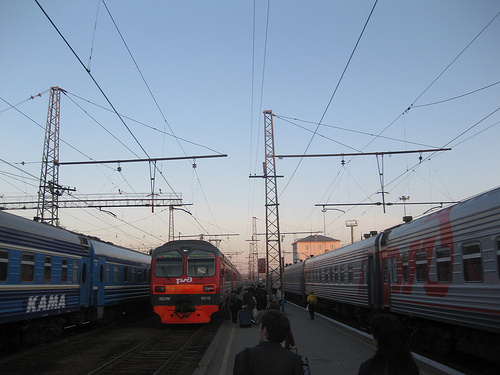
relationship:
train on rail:
[152, 237, 243, 324] [83, 290, 230, 374]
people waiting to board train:
[233, 300, 253, 329] [152, 235, 252, 326]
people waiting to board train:
[257, 283, 267, 310] [152, 235, 252, 326]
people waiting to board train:
[226, 294, 241, 322] [152, 235, 252, 326]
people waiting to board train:
[243, 284, 253, 306] [152, 235, 252, 326]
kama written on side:
[21, 290, 72, 315] [6, 226, 86, 283]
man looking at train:
[224, 309, 305, 372] [145, 226, 239, 329]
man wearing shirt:
[230, 309, 311, 375] [305, 294, 318, 300]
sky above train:
[4, 0, 494, 272] [151, 242, 234, 319]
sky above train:
[4, 0, 494, 272] [293, 206, 499, 316]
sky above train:
[4, 0, 494, 272] [0, 207, 150, 326]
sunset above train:
[88, 233, 423, 275] [271, 185, 497, 329]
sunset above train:
[88, 233, 423, 275] [152, 237, 243, 324]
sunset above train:
[88, 233, 423, 275] [0, 212, 151, 349]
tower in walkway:
[247, 88, 291, 321] [239, 272, 361, 372]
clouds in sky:
[30, 135, 471, 254] [0, 0, 498, 188]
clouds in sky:
[55, 200, 395, 277] [4, 0, 494, 272]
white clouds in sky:
[101, 72, 304, 216] [4, 0, 494, 272]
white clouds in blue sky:
[338, 49, 420, 126] [208, 31, 348, 101]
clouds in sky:
[254, 78, 378, 179] [424, 24, 477, 55]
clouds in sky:
[312, 93, 494, 184] [4, 0, 494, 272]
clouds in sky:
[73, 202, 416, 275] [4, 0, 494, 272]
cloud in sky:
[318, 203, 410, 248] [4, 0, 494, 272]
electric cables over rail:
[0, 0, 499, 270] [83, 290, 230, 374]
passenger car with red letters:
[374, 182, 499, 337] [356, 200, 457, 306]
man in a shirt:
[230, 309, 311, 375] [303, 293, 322, 304]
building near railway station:
[288, 227, 358, 267] [0, 155, 499, 374]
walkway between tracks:
[277, 274, 372, 369] [298, 293, 418, 360]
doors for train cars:
[77, 257, 110, 315] [2, 211, 154, 337]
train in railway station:
[152, 237, 243, 324] [17, 70, 477, 370]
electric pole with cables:
[259, 109, 284, 309] [268, 107, 440, 155]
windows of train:
[11, 253, 86, 286] [4, 206, 154, 334]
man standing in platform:
[230, 309, 311, 375] [191, 280, 465, 373]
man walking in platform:
[230, 309, 311, 375] [191, 280, 465, 373]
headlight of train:
[151, 280, 215, 294] [147, 238, 248, 333]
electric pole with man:
[259, 107, 289, 309] [230, 309, 311, 375]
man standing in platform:
[230, 309, 311, 375] [173, 265, 462, 373]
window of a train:
[155, 257, 181, 277] [152, 237, 243, 324]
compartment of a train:
[87, 239, 95, 307] [0, 207, 150, 326]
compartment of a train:
[91, 256, 126, 305] [0, 207, 150, 326]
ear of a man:
[261, 315, 268, 332] [234, 307, 311, 372]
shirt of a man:
[305, 294, 318, 300] [305, 284, 318, 318]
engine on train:
[153, 291, 214, 323] [152, 237, 243, 324]